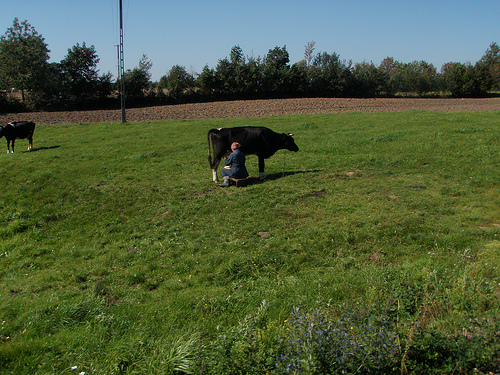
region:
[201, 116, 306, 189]
Cow in the meadow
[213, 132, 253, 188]
Person milking a cow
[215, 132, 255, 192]
Person wears a blue jacket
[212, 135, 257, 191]
Person is sitting on a stool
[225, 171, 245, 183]
Stool is brown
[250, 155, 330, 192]
Shadow cast on the green grass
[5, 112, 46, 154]
Cow stand on a cow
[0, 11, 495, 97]
Trees are green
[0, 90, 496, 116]
Fence on the field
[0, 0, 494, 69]
Sky is blue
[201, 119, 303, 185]
black cow with white feet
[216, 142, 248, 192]
person milking a black cow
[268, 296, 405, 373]
patch of blue flowers in a field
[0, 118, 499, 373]
green field of grass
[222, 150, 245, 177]
person's blue colored outfit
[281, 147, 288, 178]
rope hanging from a cow's neck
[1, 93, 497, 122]
area of brown tilled soil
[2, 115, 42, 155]
black cow standing in a field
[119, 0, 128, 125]
tall metal tower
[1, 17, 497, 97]
line of green trees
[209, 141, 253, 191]
person is milking the black cow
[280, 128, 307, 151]
cow's head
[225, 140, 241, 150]
head wrap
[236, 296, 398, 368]
purple plants in the grass pasture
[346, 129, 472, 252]
grass pasture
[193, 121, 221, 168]
cow's tail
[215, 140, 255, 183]
person wearing a blue outfit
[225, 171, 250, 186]
wooden rectangular seat that the person is sitting on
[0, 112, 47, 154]
cow behind the other cow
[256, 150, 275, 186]
front legs on the black cow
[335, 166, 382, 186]
small brown spot on grass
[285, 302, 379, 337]
tiny flower buds in field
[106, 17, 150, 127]
large electrical tower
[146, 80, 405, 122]
brown section of field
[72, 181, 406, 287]
green grass in field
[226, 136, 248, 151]
man wearing red hat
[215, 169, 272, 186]
man sitting on bench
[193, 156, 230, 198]
white feet on cow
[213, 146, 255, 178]
man wearing blue clothing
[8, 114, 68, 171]
large cow standing in field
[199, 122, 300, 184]
a black cow in a field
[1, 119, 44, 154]
a black cow in a field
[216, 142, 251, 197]
a person milking a cow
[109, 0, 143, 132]
a tall post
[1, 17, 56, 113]
a green tree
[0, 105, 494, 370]
green grass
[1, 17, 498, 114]
many trees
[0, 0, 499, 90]
a blue sky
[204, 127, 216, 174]
a cow's tail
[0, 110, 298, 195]
two cows and their owner